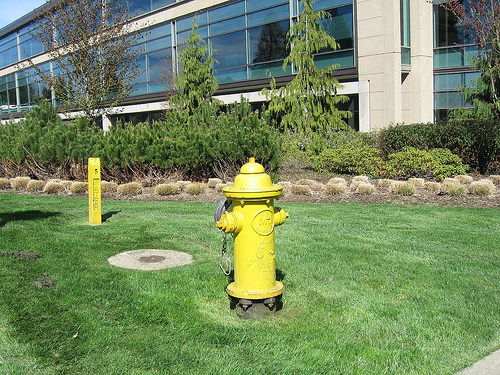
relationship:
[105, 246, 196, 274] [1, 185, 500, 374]
cement on lawn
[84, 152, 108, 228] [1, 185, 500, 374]
pole in lawn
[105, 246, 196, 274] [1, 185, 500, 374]
cement in lawn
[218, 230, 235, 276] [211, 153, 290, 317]
chain on hydrant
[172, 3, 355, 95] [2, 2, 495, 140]
windows on building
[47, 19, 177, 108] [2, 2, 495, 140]
windows on building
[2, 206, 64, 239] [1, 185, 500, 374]
shadow on lawn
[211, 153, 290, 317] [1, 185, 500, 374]
hydrant on lawn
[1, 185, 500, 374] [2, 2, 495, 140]
lawn in front of building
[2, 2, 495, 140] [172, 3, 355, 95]
building with windows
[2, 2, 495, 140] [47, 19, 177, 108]
building with windows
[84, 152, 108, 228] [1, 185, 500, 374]
pole on lawn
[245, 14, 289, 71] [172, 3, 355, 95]
reflections in windows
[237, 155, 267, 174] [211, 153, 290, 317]
knob on hydrant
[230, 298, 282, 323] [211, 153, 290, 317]
base of hydrant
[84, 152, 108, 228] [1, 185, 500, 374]
pole out of lawn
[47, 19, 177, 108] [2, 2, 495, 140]
windows along building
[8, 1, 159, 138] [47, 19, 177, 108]
tree in front of windows